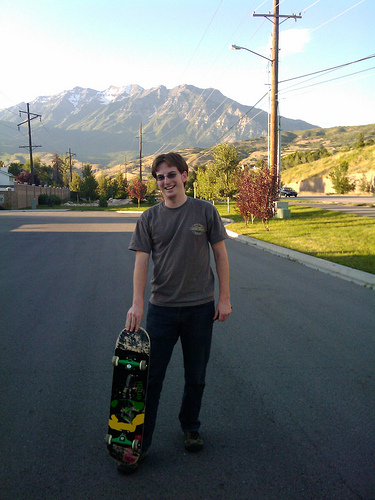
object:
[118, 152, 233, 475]
man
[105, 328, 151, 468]
skateboard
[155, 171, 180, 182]
glasses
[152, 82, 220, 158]
mountains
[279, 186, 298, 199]
car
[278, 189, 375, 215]
road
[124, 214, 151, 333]
arm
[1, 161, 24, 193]
houses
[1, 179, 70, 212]
fence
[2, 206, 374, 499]
street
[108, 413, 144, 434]
paint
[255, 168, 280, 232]
tree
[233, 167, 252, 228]
tree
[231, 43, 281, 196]
light post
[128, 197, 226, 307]
shirt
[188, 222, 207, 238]
logo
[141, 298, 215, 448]
jeans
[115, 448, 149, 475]
foot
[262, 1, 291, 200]
power pole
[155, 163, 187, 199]
face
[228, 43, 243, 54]
streetlight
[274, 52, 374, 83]
power lines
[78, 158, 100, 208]
trees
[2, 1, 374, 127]
sky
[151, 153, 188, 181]
hair